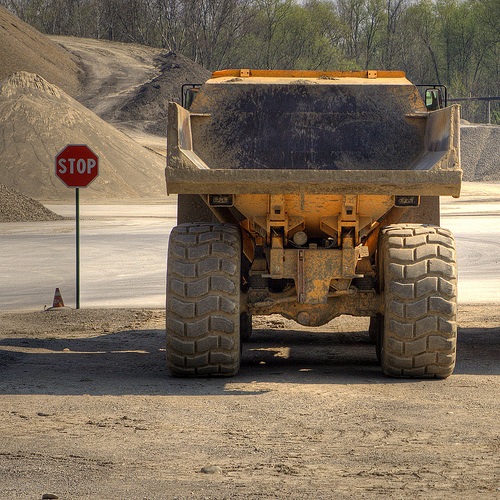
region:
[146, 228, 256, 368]
the tires are huge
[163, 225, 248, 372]
the tire is brown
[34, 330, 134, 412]
shadow is on the ground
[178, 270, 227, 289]
the spaces are huge on the tire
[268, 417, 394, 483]
tire tracks are on the ground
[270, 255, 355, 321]
the metal is yellow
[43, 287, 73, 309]
the cone is yellow and white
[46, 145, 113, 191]
the stop sign is octagon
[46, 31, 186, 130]
the road is winding up the hill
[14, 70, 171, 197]
the hill is pointy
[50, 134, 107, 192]
a red stop sign on a pole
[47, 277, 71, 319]
a traffic cone by the pole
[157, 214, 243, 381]
a large wheel on the tractor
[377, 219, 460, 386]
the tractor has a right wheel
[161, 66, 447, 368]
this tractor is yellow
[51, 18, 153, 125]
a dirt road on the hill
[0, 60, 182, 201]
a pile of dirt by the road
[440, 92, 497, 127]
a fence across the road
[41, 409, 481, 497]
tire tracks in the dirt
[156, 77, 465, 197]
the tractor bed is empty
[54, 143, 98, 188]
red stop sign on the field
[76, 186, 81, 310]
green pole holding a stop sign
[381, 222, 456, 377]
rear right wheel of a truck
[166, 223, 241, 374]
rear left wheel of a truck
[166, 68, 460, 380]
big yellow truck by a stop sign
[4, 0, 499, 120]
lots of trees in the background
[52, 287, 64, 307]
orange and white cone by the stop sign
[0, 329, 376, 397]
shadow of a big truck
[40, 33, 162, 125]
dirt road going uphill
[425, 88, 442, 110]
mirror on the right of the truck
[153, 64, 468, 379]
A large yellow truck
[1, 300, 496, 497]
A bed of gravel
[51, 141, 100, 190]
A stop sign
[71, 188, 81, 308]
A metal pole in the ground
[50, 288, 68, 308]
a white and orange traffic cone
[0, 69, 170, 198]
A large pile of gravel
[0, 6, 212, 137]
A large pile of gravel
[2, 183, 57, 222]
A pile of gravel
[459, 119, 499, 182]
A large pile of gravel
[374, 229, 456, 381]
Right wheel of this machine.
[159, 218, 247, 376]
Left wheel of this machine.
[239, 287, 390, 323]
Rear axle of this machine.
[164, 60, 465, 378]
A very large dump truck.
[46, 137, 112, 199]
This is a red stop sign.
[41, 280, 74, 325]
A traffic cone sitting there.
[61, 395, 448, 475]
The dirt and the sand.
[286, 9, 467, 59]
Green trees growing up.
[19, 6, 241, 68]
Dead trees dying out.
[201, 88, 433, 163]
Empty bed of a dump truck.